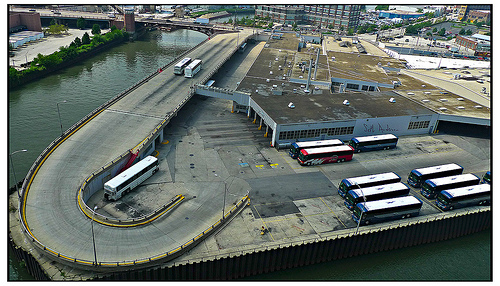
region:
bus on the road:
[351, 195, 419, 215]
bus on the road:
[361, 185, 403, 200]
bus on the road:
[341, 172, 396, 184]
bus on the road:
[435, 187, 484, 202]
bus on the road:
[428, 172, 479, 188]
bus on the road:
[413, 161, 455, 176]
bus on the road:
[295, 149, 354, 169]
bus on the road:
[294, 138, 341, 145]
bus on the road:
[358, 133, 390, 148]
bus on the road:
[122, 157, 151, 195]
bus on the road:
[423, 175, 471, 183]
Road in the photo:
[82, 121, 144, 148]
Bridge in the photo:
[77, 79, 197, 170]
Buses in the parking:
[341, 162, 481, 215]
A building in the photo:
[247, 101, 434, 136]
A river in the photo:
[71, 63, 141, 95]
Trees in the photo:
[50, 42, 97, 64]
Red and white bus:
[295, 143, 375, 170]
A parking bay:
[262, 190, 324, 230]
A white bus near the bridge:
[95, 152, 172, 197]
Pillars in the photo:
[297, 42, 332, 89]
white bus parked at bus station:
[101, 153, 162, 203]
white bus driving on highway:
[183, 57, 205, 79]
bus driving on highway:
[171, 53, 192, 75]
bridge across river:
[0, 0, 257, 53]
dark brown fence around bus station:
[6, 175, 496, 285]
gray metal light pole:
[7, 145, 31, 205]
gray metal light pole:
[52, 96, 72, 141]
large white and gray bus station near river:
[231, 25, 494, 160]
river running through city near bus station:
[6, 8, 260, 201]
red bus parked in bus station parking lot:
[294, 142, 355, 167]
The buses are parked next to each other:
[290, 128, 485, 220]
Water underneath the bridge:
[1, 17, 219, 190]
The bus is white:
[107, 149, 157, 210]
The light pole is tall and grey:
[86, 202, 109, 277]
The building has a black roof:
[243, 37, 486, 137]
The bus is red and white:
[297, 146, 355, 168]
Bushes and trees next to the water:
[13, 25, 133, 93]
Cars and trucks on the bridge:
[72, 9, 256, 41]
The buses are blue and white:
[343, 162, 487, 224]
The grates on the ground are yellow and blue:
[237, 159, 282, 171]